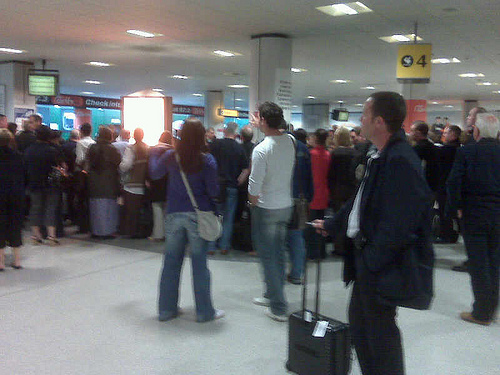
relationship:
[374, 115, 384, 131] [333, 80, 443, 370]
ear on man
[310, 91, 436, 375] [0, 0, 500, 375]
man standing in airport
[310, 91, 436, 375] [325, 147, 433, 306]
man wearing jacket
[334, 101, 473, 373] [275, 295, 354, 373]
man with suitcase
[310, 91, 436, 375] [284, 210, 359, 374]
man with suitcase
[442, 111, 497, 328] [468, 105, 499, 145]
man with head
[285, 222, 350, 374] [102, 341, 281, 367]
case on floor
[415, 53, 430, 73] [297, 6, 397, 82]
4 on ceiling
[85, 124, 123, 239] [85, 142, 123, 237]
woman in dress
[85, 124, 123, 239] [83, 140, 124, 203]
woman in coat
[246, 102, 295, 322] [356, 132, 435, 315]
man wearing jacket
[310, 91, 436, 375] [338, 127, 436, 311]
man in jacket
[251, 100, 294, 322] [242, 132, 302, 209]
man in shirt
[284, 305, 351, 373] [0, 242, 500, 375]
case on floor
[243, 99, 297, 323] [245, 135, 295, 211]
man in shirt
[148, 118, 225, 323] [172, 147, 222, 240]
woman carrying bag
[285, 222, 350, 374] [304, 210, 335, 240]
case in hand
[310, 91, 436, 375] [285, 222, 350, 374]
man has case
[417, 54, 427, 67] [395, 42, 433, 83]
4 on sign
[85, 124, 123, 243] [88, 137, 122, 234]
woman wearing dress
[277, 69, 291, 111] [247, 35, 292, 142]
column pasted to pillar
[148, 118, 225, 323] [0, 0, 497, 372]
woman standing in airport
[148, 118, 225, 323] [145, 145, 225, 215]
woman wearing blue shirt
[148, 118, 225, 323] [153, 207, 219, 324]
woman wearing jeans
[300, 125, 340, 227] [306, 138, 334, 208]
lady wearing sweater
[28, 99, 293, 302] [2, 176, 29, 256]
woman wearing pants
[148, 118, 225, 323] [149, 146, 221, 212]
woman in blue shirt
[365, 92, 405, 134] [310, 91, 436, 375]
brown hair on man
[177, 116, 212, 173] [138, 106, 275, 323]
hair on woman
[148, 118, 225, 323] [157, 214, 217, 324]
woman in jeans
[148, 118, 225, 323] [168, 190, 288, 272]
woman has bag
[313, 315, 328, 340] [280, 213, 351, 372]
tag on suit case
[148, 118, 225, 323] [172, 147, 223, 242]
woman with a bag